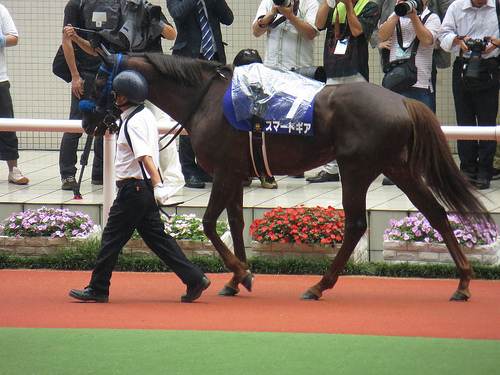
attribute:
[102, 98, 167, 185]
shirt — white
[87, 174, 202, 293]
pants — black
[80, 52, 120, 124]
harness — blue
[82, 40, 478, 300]
horse — large, brown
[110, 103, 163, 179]
shirt — white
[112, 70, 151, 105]
helmet — black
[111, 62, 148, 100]
man's helmet — black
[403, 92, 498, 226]
horse's tail — brown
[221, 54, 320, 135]
horse's saddle — blue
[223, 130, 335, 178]
horse's belly — brown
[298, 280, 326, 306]
horse's hoof — black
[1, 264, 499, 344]
ground — orange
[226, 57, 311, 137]
saddle — taped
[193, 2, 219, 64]
tie — blue, white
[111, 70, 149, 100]
head gear — dark, blue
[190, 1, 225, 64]
blue tie — white